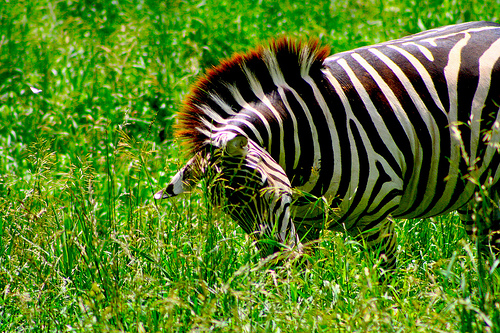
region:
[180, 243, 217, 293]
part of some grass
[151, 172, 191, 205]
edge of an ear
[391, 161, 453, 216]
part of a stomach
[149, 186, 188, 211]
edge of an ear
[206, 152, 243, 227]
head of a zebra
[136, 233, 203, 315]
part of a grass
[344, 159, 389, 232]
part of a zebra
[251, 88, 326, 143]
part of a neck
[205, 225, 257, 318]
part of a zebra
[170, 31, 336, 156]
the mane of a zebra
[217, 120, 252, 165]
the ear of a zebra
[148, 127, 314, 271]
the head of a zebra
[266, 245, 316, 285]
the nose of a zebra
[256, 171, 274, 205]
the eye of a zebra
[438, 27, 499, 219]
a black stripe on the zebra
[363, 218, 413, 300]
the leg of a zebra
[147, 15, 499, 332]
a black and white zebra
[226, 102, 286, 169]
the neck of the zebra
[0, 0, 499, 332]
a green grassy field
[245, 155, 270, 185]
the eye of a zebra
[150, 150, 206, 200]
the ear of a zebra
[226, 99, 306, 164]
the neck of a zebra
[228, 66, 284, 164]
a black stripe on the zebra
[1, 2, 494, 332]
a grassy green field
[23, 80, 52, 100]
a white flower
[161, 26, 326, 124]
brown and black mane on zebra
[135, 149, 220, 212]
zebras black and white right ear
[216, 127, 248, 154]
zebras black ans white left ear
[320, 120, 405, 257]
zebras black and white striped shoulder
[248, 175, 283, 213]
zebras black eye ball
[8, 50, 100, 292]
tall grass the zebra is standing in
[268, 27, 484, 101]
back bone of the zebra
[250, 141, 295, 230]
zebras black and white large jaw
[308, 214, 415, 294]
zebras left front leg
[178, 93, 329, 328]
black and white zebras head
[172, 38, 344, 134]
the black and white mane of a zebra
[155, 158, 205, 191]
the black and white ear of a zebra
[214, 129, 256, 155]
the black and white ear of a zebra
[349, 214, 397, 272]
the black and white leg of a zebra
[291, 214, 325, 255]
the black and white leg of a zebra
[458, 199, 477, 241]
the black and white leg of a zebra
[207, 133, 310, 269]
the black and white head of a zebra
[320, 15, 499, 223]
the black and white body of a zebra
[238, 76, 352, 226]
the black and white neck of a zebra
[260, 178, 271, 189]
the eye of a zebra